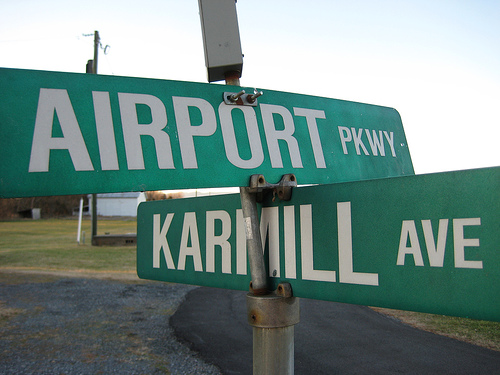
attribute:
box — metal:
[195, 1, 255, 83]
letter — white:
[225, 84, 271, 174]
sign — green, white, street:
[119, 102, 337, 180]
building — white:
[61, 160, 176, 234]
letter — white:
[88, 88, 121, 170]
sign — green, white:
[0, 66, 413, 201]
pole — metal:
[238, 280, 308, 372]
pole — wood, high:
[87, 31, 99, 251]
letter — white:
[118, 86, 176, 177]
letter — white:
[259, 101, 304, 169]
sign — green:
[102, 130, 494, 344]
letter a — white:
[28, 87, 95, 171]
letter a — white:
[395, 217, 422, 267]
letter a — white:
[176, 212, 203, 273]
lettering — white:
[27, 86, 337, 181]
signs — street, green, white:
[1, 61, 498, 326]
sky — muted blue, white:
[4, 5, 499, 198]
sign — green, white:
[133, 160, 498, 322]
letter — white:
[87, 84, 129, 180]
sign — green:
[2, 49, 485, 329]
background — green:
[6, 69, 422, 193]